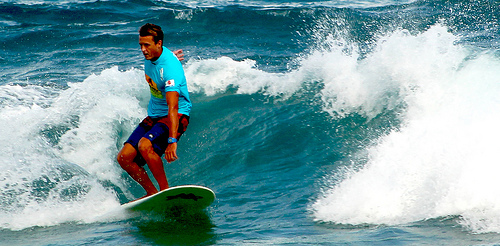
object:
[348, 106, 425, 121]
ground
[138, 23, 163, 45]
hair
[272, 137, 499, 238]
water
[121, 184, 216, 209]
surfboard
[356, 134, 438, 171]
ground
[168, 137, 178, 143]
blue watch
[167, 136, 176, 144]
wrist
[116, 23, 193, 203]
man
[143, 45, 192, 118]
t-shirt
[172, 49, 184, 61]
right hand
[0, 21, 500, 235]
wave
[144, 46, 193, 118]
shirt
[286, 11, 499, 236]
wave foam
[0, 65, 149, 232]
wave foam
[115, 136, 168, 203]
legs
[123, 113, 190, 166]
shorts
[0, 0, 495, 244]
ocean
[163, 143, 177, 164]
hand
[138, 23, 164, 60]
head